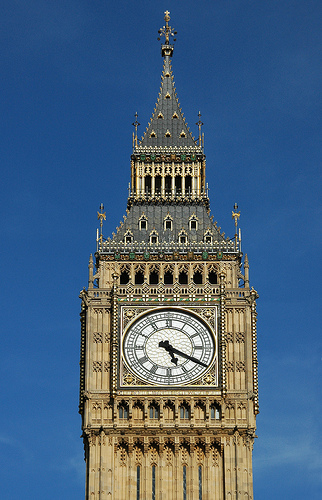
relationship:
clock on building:
[116, 302, 223, 386] [78, 10, 260, 500]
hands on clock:
[156, 337, 211, 377] [116, 302, 223, 386]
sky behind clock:
[1, 4, 321, 476] [116, 302, 223, 386]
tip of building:
[149, 6, 189, 59] [78, 10, 260, 500]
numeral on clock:
[162, 316, 180, 333] [116, 302, 223, 386]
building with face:
[78, 10, 260, 500] [127, 312, 212, 385]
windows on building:
[142, 173, 202, 195] [58, 7, 321, 489]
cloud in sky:
[254, 428, 321, 478] [1, 4, 321, 476]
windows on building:
[142, 173, 202, 195] [78, 10, 260, 500]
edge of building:
[126, 105, 142, 154] [78, 10, 260, 500]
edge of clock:
[126, 105, 142, 154] [116, 302, 223, 386]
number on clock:
[179, 319, 190, 332] [116, 302, 223, 386]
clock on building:
[116, 302, 223, 386] [58, 7, 321, 489]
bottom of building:
[75, 433, 258, 497] [58, 7, 321, 489]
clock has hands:
[116, 302, 223, 386] [156, 337, 211, 377]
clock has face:
[116, 302, 223, 386] [127, 312, 212, 385]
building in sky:
[78, 10, 260, 500] [1, 4, 321, 476]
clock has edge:
[116, 302, 223, 386] [126, 105, 142, 154]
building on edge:
[78, 10, 260, 500] [126, 105, 142, 154]